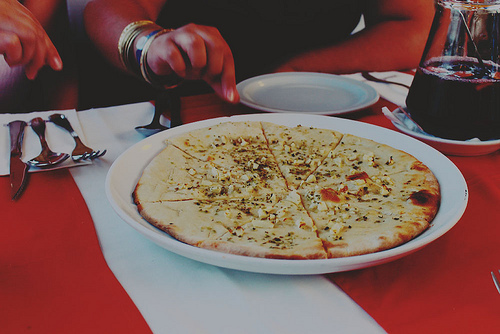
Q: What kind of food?
A: Pizza.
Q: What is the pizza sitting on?
A: Plate.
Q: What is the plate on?
A: Table.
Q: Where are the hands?
A: In front of silverware and plate.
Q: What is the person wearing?
A: Shirt.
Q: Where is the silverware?
A: On napkin.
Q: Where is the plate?
A: On table.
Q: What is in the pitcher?
A: Liquid.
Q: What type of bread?
A: Flat bread.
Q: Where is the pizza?
A: On plate.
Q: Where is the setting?
A: Restaurant.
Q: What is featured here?
A: A light type of pizza.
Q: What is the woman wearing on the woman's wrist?
A: Bracelets.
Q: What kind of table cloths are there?
A: Red table cloths.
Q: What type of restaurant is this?
A: Italian.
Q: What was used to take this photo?
A: A telephoto lens.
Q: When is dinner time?
A: Now.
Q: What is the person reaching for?
A: Pizza.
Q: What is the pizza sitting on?
A: A white plate.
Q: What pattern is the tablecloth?
A: Stripes.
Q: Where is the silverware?
A: On the left.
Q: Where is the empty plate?
A: Behind the pizza.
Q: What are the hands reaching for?
A: Pizza.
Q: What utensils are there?
A: Spoon, fork, and knife.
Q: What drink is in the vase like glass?
A: Wine.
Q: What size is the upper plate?
A: Small.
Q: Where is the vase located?
A: Plate.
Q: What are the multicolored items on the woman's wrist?
A: Bracelets.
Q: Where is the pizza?
A: On a plate.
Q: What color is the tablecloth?
A: Red.